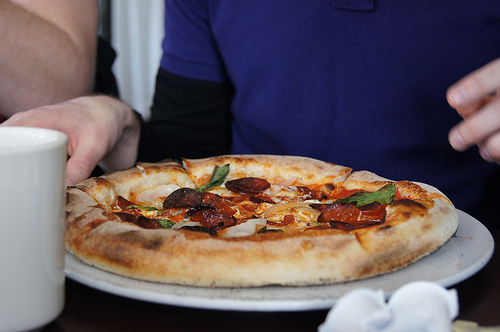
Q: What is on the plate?
A: Pizza.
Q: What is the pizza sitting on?
A: White plate.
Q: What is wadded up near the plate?
A: Napkin.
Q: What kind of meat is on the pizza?
A: Pepperoni.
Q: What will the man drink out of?
A: The mug.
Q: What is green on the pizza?
A: Basil.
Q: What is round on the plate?
A: Pizza.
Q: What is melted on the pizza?
A: Cheese.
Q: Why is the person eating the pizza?
A: Hungry.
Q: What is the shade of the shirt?
A: Blue with black sleeves.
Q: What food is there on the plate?
A: Pizza.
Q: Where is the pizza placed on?
A: On the plate.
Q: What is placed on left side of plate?
A: Coffee mug.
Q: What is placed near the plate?
A: Mug.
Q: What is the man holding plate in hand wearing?
A: Blue shirt.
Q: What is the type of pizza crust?
A: Brown crust.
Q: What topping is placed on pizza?
A: Red pepperoni.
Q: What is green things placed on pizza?
A: Leaves.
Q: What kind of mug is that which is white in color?
A: Coffee mug.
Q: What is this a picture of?
A: A white porcelain plate.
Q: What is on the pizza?
A: Toppings.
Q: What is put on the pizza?
A: Marina sauce.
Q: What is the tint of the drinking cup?
A: White.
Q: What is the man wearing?
A: A blue shirt.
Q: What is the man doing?
A: Going to eat a pizza.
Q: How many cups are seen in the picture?
A: One.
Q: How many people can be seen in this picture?
A: Two.